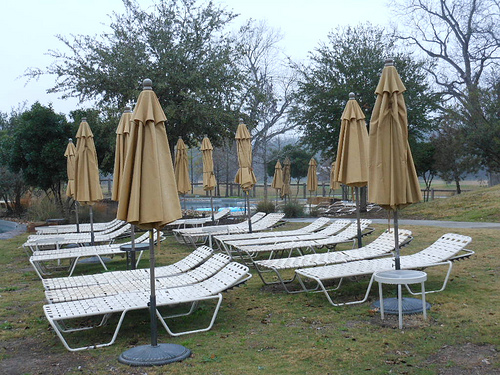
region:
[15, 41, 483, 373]
all umbrellas brown, & the chaises are white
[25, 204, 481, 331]
all chaise longues lounging near-flatly & w/ no-one at all on them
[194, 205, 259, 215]
a sliver of blue swimming pool in the distance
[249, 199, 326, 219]
two bushes in front of two umbrellas, & a third starting up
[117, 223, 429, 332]
2 or 3, maybe 4, little round tables amid the longues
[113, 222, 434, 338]
all tables are one or another monochrome, all are bare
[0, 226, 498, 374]
grass beneath summer party furniture is turning yellow+sparse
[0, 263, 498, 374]
dark seeds litter foreground, dragged by animals or blown by wind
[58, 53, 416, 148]
umbrellas topped w/ round little silvertone things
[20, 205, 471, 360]
longue legs are not long, but they have rounded edges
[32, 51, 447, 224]
numerous brown umbrellas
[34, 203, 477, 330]
white chairs for laying out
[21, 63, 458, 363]
chairs with brown umbrellas to go along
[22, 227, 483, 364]
grass that is browning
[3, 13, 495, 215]
group of big and small trees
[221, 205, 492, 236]
path way through the grass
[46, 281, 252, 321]
white chair with holes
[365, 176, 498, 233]
short grassy hill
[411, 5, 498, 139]
tree with no leaves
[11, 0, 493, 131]
dull light sky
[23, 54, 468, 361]
lounge chairs and umbrellas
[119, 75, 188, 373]
a self standing umbrella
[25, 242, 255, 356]
three lounge chairs on grass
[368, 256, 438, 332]
a small side table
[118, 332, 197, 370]
the base of an umbrella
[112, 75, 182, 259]
the fabric of a umbrella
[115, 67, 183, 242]
a brown umbrella that is closed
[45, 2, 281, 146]
a tree behind the chairs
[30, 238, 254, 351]
unoccupied lounge chairs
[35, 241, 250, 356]
lounge chairs in the reclined position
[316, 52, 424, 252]
the umbrellas are closed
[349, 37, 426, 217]
the umbrella is beige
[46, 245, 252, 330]
the chairs are white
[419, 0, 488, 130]
the tree is bare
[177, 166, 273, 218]
the pool is blue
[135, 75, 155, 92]
a ball on top of the umbrella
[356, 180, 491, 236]
the walkway is grey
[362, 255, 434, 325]
a small white table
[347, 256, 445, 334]
the table top is glass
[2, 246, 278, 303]
the chairs have small square spaces in them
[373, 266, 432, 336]
table near lawn chairs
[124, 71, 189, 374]
brown umbrella on a stand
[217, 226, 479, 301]
lounge chairs near a pool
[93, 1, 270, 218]
tree behind a pool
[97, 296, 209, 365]
umbrella stand near a lounge chair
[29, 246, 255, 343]
three beach chairs near a pool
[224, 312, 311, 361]
grass in front of beach chairs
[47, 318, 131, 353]
leg of a lounge chair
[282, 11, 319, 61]
blue sky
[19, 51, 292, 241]
many closed beach umbrellas